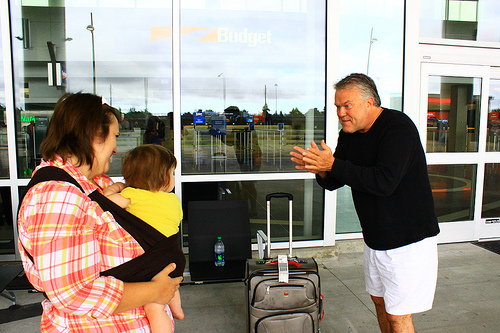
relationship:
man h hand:
[290, 72, 439, 331] [288, 141, 319, 173]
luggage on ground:
[241, 257, 329, 331] [323, 301, 358, 330]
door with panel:
[425, 75, 497, 245] [480, 162, 498, 218]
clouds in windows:
[81, 16, 320, 113] [179, 6, 326, 167]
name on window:
[219, 27, 274, 44] [9, 0, 174, 177]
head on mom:
[37, 90, 122, 180] [15, 89, 182, 333]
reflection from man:
[206, 98, 262, 280] [290, 72, 439, 331]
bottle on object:
[211, 229, 228, 267] [184, 189, 254, 283]